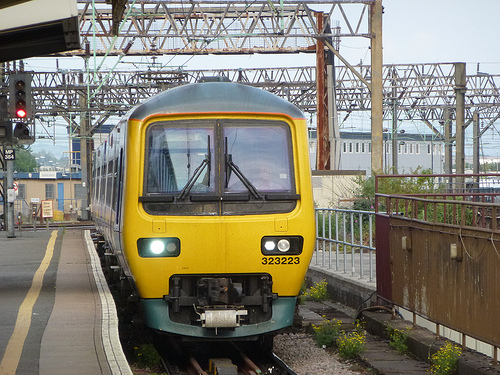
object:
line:
[0, 230, 62, 375]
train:
[86, 76, 319, 342]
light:
[148, 236, 166, 256]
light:
[274, 238, 296, 254]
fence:
[375, 169, 500, 365]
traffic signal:
[11, 69, 34, 120]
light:
[12, 106, 28, 120]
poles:
[370, 0, 386, 173]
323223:
[262, 256, 305, 266]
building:
[308, 129, 450, 173]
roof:
[308, 126, 464, 146]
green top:
[128, 75, 305, 119]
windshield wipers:
[224, 137, 270, 203]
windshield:
[139, 117, 300, 201]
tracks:
[274, 353, 299, 374]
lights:
[261, 238, 276, 251]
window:
[104, 157, 117, 210]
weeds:
[334, 321, 365, 358]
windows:
[427, 144, 432, 154]